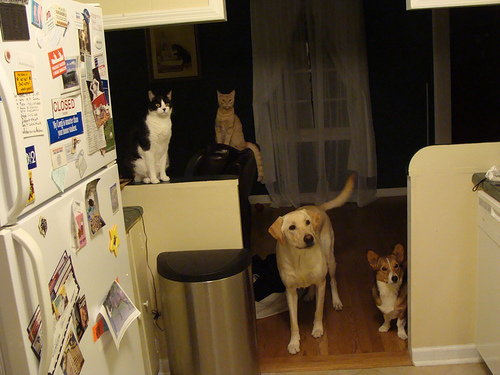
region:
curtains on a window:
[252, 42, 388, 189]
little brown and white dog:
[360, 239, 422, 341]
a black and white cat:
[118, 76, 186, 193]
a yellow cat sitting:
[203, 82, 258, 157]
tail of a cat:
[238, 134, 273, 189]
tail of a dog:
[308, 174, 378, 221]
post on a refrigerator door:
[38, 219, 133, 360]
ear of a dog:
[258, 211, 290, 248]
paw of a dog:
[273, 326, 308, 360]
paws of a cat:
[145, 168, 172, 188]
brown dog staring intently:
[267, 195, 352, 350]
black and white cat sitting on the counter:
[117, 90, 185, 189]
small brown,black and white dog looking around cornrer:
[365, 240, 413, 345]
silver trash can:
[150, 240, 262, 365]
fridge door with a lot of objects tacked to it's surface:
[12, 202, 157, 366]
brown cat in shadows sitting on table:
[202, 82, 275, 186]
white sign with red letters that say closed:
[47, 89, 84, 126]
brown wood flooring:
[344, 332, 385, 369]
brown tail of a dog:
[296, 178, 362, 218]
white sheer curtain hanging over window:
[278, 66, 364, 151]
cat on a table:
[206, 82, 259, 154]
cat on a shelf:
[122, 87, 180, 195]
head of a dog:
[264, 207, 334, 255]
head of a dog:
[364, 241, 416, 292]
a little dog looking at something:
[363, 234, 419, 341]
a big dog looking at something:
[269, 181, 351, 363]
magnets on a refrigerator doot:
[10, 33, 69, 94]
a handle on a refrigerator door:
[11, 227, 80, 374]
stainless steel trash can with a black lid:
[144, 226, 263, 374]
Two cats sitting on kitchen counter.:
[119, 76, 270, 206]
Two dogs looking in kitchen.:
[263, 176, 413, 363]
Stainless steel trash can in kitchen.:
[151, 244, 274, 374]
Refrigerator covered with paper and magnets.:
[0, 5, 144, 372]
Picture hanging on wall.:
[141, 16, 223, 84]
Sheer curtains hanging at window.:
[251, 8, 376, 205]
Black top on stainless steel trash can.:
[151, 246, 256, 281]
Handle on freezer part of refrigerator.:
[4, 85, 39, 222]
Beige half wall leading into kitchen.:
[403, 150, 475, 360]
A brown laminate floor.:
[341, 217, 386, 247]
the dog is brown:
[275, 196, 350, 278]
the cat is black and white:
[144, 93, 196, 178]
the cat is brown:
[206, 87, 278, 171]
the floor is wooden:
[352, 268, 375, 360]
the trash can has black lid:
[151, 259, 270, 373]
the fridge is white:
[21, 84, 165, 374]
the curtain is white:
[257, 78, 378, 189]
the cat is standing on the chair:
[206, 88, 271, 162]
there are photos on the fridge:
[38, 103, 114, 188]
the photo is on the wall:
[141, 36, 220, 81]